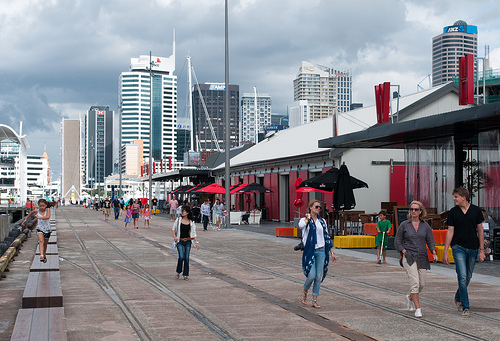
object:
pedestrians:
[104, 203, 112, 221]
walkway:
[56, 203, 500, 341]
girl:
[19, 200, 53, 262]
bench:
[22, 271, 64, 306]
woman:
[172, 207, 199, 278]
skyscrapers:
[117, 30, 180, 170]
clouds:
[0, 0, 500, 185]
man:
[445, 188, 489, 315]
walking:
[394, 200, 438, 320]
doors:
[276, 173, 293, 221]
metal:
[138, 329, 147, 341]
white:
[276, 126, 306, 154]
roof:
[212, 84, 445, 172]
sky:
[0, 0, 500, 185]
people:
[87, 196, 91, 207]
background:
[0, 0, 500, 341]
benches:
[10, 306, 66, 341]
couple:
[201, 198, 230, 230]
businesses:
[140, 165, 210, 212]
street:
[53, 203, 500, 341]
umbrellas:
[192, 182, 222, 194]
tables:
[228, 210, 262, 225]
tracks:
[57, 205, 108, 288]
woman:
[294, 198, 338, 308]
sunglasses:
[180, 209, 186, 214]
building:
[211, 82, 479, 224]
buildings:
[84, 105, 113, 196]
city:
[0, 0, 500, 341]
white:
[166, 62, 173, 74]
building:
[60, 117, 84, 202]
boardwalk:
[96, 217, 375, 341]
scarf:
[301, 216, 317, 277]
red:
[196, 182, 234, 193]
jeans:
[174, 239, 190, 275]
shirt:
[448, 203, 484, 249]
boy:
[373, 209, 391, 266]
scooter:
[377, 229, 387, 265]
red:
[457, 54, 474, 105]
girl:
[143, 205, 151, 228]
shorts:
[144, 215, 151, 221]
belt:
[178, 237, 195, 242]